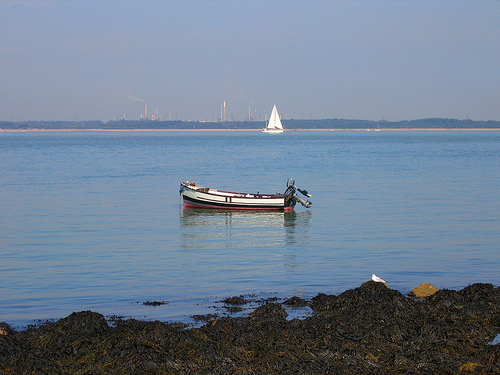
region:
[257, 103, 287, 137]
sailboat with white sail on the water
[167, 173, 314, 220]
red black and white powerboat on the water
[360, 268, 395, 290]
white bird sitting on a rock at the shoreline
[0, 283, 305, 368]
rocks with seaweed at the shoreline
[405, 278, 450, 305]
a brown rock exposed with low tide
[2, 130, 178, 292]
dark and light blue water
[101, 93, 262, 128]
power generation plant in the background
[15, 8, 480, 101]
dark gray and blue sky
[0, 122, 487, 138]
shorline across the water with small boats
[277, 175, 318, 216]
two engines tipped up on the back of the boat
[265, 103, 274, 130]
a white sail on a sailboat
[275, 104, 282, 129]
a white sail on a sailboat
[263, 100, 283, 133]
a white sailboat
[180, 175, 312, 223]
a black white and red wooden motorboat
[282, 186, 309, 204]
a black and silver motor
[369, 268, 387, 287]
a black and white seagull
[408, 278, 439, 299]
a brown rock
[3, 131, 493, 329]
a bright blue body of water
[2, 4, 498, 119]
a soft blue cloudless sky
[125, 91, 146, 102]
smoke from a stack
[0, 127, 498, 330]
The beautiful blue ocean.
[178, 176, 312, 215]
A small floating boat.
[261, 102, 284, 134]
A boat in the distance.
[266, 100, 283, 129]
The white veils of a boat.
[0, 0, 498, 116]
The beautiful sky above the earth.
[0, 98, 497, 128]
A large city is visible in the distance.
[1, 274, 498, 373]
Discarded matter from the ocean.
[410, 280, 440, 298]
A floating brown item.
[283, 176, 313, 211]
Motors meant to propel a boat.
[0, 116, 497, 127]
A large landscaping far in the distance.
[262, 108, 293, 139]
The white sailboat in the distance.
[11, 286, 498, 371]
The dark seaweed in the photo.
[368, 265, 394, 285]
The white bird on top of the pile of seaweed.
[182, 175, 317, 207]
The gray boat in the water.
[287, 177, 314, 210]
The engine of the boat.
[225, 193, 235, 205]
The two small stripes on the side of the gray boat.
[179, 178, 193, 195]
The front of the gray boat.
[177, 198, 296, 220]
The red stripe on the bottom of the gray boat.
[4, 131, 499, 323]
The water where the boats are floating.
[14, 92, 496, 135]
The trees in the far distance.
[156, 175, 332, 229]
wooden boat floating on water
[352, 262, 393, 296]
white bird sitting on rock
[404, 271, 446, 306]
brown rock in water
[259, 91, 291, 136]
white sail boat on water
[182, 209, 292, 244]
reflection of boat in water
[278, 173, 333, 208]
grey motors on back of boat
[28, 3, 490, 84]
hazy grey sky above water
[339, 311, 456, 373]
piles of debris on water shore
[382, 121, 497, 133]
brown sandy beach on water shore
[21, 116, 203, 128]
row of green trees